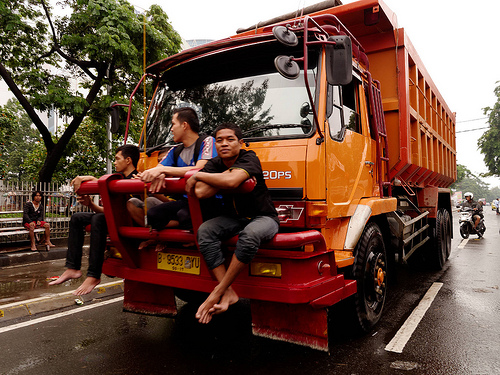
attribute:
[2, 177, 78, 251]
fence — metal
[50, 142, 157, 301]
man — young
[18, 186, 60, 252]
person — seated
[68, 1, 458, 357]
truck — large orange dump , big, bright, red, orange, large, dump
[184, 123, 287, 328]
man — barefooted, young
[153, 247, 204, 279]
license plate — yellow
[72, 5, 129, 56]
leaves — green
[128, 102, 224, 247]
man — barefooted, young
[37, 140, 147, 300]
man — barefooted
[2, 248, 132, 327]
sidewalk — wet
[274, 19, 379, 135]
mirrors — set 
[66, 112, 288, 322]
boys — Three 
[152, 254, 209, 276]
plate — License 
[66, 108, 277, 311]
boys — barefoot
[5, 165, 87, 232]
fence — metal 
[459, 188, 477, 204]
helmet — white 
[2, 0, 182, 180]
tree — large  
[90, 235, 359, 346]
bar — metal , red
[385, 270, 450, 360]
stripe — white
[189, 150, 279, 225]
top — black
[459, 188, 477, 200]
helmet — white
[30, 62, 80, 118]
tree — green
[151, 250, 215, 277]
plate — number, yellow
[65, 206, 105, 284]
pants — black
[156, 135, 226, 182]
top — blue, grey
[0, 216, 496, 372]
road — wet, rain slicked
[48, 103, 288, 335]
men — three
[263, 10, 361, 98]
mirrors — side view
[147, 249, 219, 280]
tag — yellow, black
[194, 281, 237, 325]
feet — bare